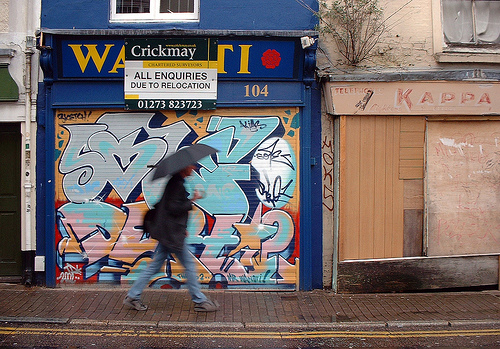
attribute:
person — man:
[126, 139, 223, 316]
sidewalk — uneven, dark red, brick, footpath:
[8, 281, 499, 348]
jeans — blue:
[129, 240, 206, 301]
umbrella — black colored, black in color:
[156, 140, 222, 198]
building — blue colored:
[34, 8, 323, 290]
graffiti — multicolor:
[57, 105, 299, 290]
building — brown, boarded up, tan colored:
[317, 3, 500, 292]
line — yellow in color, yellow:
[5, 323, 500, 339]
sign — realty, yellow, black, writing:
[124, 38, 222, 110]